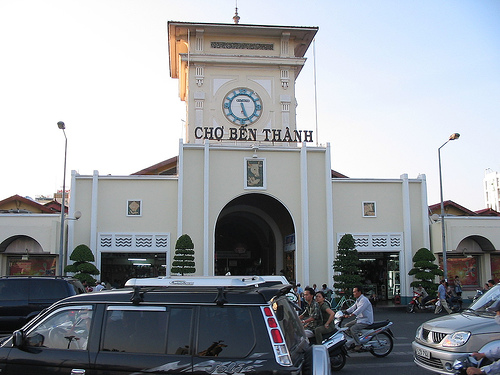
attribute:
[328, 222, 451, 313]
trees — unusual, trimmed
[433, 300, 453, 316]
pants — khaki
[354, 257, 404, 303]
entrance — small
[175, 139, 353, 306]
market — large, asian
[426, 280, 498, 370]
suv — silver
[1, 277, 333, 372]
suv — black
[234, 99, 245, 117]
hands — blue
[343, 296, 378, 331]
shirt — white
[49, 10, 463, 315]
building — Yellow, white, large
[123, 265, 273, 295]
rack — silver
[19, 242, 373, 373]
station wagon — black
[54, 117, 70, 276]
light pole — tall, street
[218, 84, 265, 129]
clock face —   white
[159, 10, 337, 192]
building —  yellow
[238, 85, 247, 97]
number — blue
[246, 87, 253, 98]
number — blue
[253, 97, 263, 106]
number — blue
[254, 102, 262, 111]
number — blue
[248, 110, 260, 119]
number — blue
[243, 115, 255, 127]
number — blue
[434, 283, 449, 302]
shirt —  blue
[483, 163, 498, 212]
building — tall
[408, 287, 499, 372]
gray vehicle — silver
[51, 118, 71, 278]
pole — silver, for light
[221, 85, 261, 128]
clock — white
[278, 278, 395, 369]
people — riding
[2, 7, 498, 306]
building — beige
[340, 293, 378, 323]
shirt — blue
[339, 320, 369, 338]
pants — khaki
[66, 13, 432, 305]
building — yellow